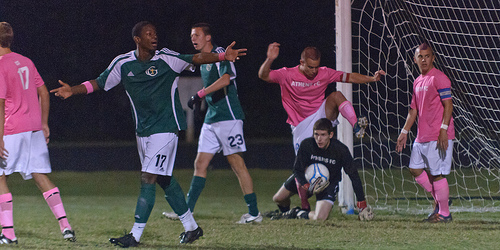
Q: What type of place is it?
A: It is a field.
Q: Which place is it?
A: It is a field.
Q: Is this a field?
A: Yes, it is a field.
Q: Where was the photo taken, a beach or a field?
A: It was taken at a field.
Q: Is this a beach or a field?
A: It is a field.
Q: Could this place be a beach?
A: No, it is a field.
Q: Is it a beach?
A: No, it is a field.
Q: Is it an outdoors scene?
A: Yes, it is outdoors.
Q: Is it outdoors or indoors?
A: It is outdoors.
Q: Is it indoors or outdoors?
A: It is outdoors.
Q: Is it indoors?
A: No, it is outdoors.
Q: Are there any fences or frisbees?
A: No, there are no fences or frisbees.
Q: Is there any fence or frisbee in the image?
A: No, there are no fences or frisbees.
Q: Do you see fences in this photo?
A: No, there are no fences.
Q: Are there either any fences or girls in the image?
A: No, there are no fences or girls.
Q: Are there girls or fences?
A: No, there are no fences or girls.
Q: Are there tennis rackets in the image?
A: No, there are no tennis rackets.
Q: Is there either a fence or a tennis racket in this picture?
A: No, there are no rackets or fences.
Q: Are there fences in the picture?
A: No, there are no fences.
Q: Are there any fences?
A: No, there are no fences.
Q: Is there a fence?
A: No, there are no fences.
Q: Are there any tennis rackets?
A: No, there are no tennis rackets.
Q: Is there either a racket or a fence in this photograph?
A: No, there are no rackets or fences.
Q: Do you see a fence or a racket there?
A: No, there are no rackets or fences.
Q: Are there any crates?
A: No, there are no crates.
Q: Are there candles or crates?
A: No, there are no crates or candles.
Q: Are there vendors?
A: No, there are no vendors.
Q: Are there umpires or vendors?
A: No, there are no vendors or umpires.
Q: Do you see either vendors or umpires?
A: No, there are no vendors or umpires.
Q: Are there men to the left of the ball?
A: Yes, there is a man to the left of the ball.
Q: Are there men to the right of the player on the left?
A: Yes, there is a man to the right of the player.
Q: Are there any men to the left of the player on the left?
A: No, the man is to the right of the player.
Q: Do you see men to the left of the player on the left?
A: No, the man is to the right of the player.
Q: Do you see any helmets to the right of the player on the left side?
A: No, there is a man to the right of the player.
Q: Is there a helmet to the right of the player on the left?
A: No, there is a man to the right of the player.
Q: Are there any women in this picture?
A: No, there are no women.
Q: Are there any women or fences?
A: No, there are no women or fences.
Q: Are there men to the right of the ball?
A: Yes, there is a man to the right of the ball.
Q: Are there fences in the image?
A: No, there are no fences.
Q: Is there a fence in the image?
A: No, there are no fences.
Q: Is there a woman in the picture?
A: No, there are no women.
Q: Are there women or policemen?
A: No, there are no women or policemen.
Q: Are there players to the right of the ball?
A: No, the player is to the left of the ball.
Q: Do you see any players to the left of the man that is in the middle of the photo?
A: Yes, there is a player to the left of the man.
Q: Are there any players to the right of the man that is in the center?
A: No, the player is to the left of the man.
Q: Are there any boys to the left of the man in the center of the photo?
A: No, there is a player to the left of the man.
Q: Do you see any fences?
A: No, there are no fences.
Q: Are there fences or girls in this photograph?
A: No, there are no fences or girls.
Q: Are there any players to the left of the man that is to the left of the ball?
A: Yes, there is a player to the left of the man.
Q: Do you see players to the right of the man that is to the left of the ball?
A: No, the player is to the left of the man.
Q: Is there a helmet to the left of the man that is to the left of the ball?
A: No, there is a player to the left of the man.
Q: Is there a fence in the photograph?
A: No, there are no fences.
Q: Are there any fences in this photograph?
A: No, there are no fences.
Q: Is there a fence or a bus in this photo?
A: No, there are no fences or buses.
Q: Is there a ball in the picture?
A: Yes, there is a ball.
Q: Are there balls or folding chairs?
A: Yes, there is a ball.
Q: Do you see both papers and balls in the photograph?
A: No, there is a ball but no papers.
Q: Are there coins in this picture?
A: No, there are no coins.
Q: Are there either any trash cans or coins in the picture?
A: No, there are no coins or trash cans.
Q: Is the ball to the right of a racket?
A: No, the ball is to the right of a man.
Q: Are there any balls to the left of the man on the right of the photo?
A: Yes, there is a ball to the left of the man.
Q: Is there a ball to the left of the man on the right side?
A: Yes, there is a ball to the left of the man.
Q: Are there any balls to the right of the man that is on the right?
A: No, the ball is to the left of the man.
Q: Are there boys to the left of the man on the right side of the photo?
A: No, there is a ball to the left of the man.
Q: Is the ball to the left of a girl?
A: No, the ball is to the left of a man.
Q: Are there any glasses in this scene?
A: No, there are no glasses.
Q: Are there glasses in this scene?
A: No, there are no glasses.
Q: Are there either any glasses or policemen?
A: No, there are no glasses or policemen.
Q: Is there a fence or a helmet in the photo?
A: No, there are no fences or helmets.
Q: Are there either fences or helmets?
A: No, there are no fences or helmets.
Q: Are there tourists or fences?
A: No, there are no fences or tourists.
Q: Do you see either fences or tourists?
A: No, there are no fences or tourists.